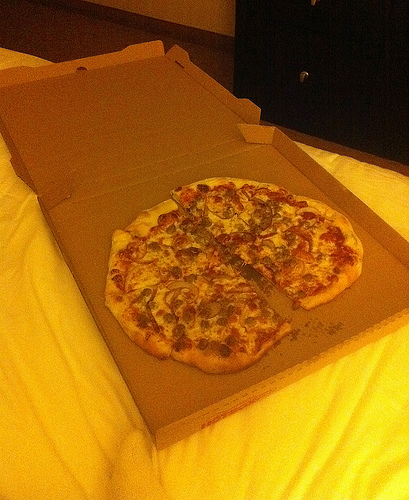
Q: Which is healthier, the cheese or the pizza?
A: The cheese is healthier than the pizza.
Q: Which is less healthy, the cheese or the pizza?
A: The pizza is less healthy than the cheese.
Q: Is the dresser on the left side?
A: No, the dresser is on the right of the image.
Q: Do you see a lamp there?
A: No, there are no lamps.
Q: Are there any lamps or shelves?
A: No, there are no lamps or shelves.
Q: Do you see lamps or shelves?
A: No, there are no lamps or shelves.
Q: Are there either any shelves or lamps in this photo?
A: No, there are no lamps or shelves.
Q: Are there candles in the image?
A: No, there are no candles.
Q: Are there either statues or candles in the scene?
A: No, there are no candles or statues.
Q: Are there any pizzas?
A: Yes, there is a pizza.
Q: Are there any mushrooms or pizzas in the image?
A: Yes, there is a pizza.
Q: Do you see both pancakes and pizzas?
A: No, there is a pizza but no pancakes.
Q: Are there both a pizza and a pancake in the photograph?
A: No, there is a pizza but no pancakes.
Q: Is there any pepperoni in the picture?
A: No, there is no pepperoni.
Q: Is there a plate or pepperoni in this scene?
A: No, there are no pepperoni or plates.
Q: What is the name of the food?
A: The food is a pizza.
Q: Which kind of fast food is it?
A: The food is a pizza.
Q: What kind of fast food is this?
A: This is a pizza.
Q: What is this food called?
A: This is a pizza.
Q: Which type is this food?
A: This is a pizza.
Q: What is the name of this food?
A: This is a pizza.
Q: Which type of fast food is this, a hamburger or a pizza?
A: This is a pizza.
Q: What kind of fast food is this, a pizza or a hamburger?
A: This is a pizza.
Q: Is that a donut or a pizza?
A: That is a pizza.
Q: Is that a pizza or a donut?
A: That is a pizza.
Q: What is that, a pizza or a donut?
A: That is a pizza.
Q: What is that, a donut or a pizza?
A: That is a pizza.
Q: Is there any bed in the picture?
A: Yes, there is a bed.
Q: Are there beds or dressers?
A: Yes, there is a bed.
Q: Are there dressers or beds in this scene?
A: Yes, there is a bed.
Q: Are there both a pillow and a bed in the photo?
A: No, there is a bed but no pillows.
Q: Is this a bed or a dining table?
A: This is a bed.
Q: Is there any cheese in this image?
A: Yes, there is cheese.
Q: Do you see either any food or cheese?
A: Yes, there is cheese.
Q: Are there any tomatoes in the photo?
A: No, there are no tomatoes.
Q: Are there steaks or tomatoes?
A: No, there are no tomatoes or steaks.